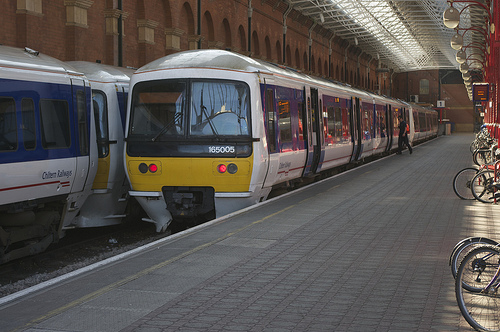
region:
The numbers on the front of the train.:
[204, 145, 240, 156]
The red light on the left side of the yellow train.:
[148, 158, 158, 174]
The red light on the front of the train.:
[214, 163, 228, 173]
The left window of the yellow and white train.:
[134, 84, 188, 139]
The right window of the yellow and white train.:
[192, 79, 252, 139]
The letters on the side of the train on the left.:
[36, 166, 81, 182]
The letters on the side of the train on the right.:
[272, 160, 298, 170]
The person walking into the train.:
[395, 115, 417, 152]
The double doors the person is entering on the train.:
[382, 98, 400, 159]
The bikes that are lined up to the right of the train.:
[456, 130, 497, 330]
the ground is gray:
[273, 210, 364, 285]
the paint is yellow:
[115, 142, 262, 207]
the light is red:
[140, 154, 163, 181]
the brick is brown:
[45, 3, 145, 47]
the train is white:
[127, 45, 452, 207]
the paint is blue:
[12, 80, 90, 174]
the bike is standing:
[442, 223, 491, 329]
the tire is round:
[450, 161, 484, 212]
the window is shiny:
[127, 64, 250, 160]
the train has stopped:
[112, 30, 444, 237]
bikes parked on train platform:
[452, 133, 496, 207]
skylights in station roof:
[373, 9, 413, 61]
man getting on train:
[386, 114, 423, 158]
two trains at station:
[56, 48, 199, 222]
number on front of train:
[204, 138, 241, 157]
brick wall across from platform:
[73, 12, 199, 52]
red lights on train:
[141, 159, 238, 179]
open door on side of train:
[302, 79, 329, 175]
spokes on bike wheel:
[462, 252, 491, 317]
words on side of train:
[33, 165, 77, 185]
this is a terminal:
[38, 10, 472, 330]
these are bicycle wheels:
[455, 222, 497, 317]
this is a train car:
[0, 50, 91, 275]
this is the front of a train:
[115, 62, 326, 242]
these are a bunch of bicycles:
[457, 127, 498, 198]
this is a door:
[292, 71, 329, 182]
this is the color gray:
[231, 224, 376, 329]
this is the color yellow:
[188, 158, 213, 179]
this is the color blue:
[22, 82, 43, 94]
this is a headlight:
[208, 162, 240, 170]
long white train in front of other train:
[121, 46, 440, 233]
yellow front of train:
[122, 155, 255, 193]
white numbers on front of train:
[207, 142, 234, 154]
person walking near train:
[392, 112, 415, 154]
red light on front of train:
[216, 162, 228, 174]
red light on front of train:
[148, 162, 155, 172]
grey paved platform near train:
[0, 125, 498, 328]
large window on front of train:
[189, 76, 251, 139]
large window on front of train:
[128, 78, 183, 135]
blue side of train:
[1, 77, 91, 165]